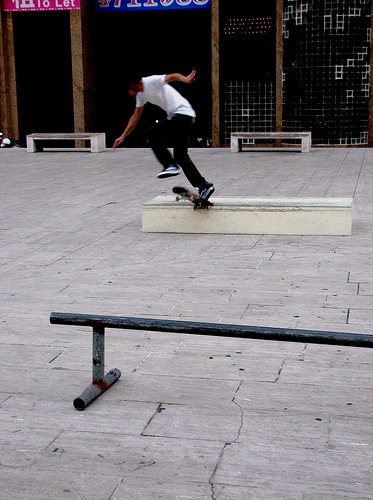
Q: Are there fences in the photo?
A: No, there are no fences.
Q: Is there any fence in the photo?
A: No, there are no fences.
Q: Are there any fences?
A: No, there are no fences.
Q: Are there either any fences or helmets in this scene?
A: No, there are no fences or helmets.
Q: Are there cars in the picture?
A: No, there are no cars.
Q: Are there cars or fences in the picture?
A: No, there are no cars or fences.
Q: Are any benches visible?
A: Yes, there is a bench.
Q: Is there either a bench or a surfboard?
A: Yes, there is a bench.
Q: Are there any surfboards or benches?
A: Yes, there is a bench.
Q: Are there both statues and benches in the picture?
A: No, there is a bench but no statues.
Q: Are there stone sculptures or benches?
A: Yes, there is a stone bench.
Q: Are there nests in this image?
A: No, there are no nests.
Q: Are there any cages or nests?
A: No, there are no nests or cages.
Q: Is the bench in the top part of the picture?
A: Yes, the bench is in the top of the image.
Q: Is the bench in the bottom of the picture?
A: No, the bench is in the top of the image.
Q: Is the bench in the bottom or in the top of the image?
A: The bench is in the top of the image.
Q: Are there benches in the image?
A: Yes, there is a bench.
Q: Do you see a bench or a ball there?
A: Yes, there is a bench.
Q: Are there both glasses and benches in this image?
A: No, there is a bench but no glasses.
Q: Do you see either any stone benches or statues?
A: Yes, there is a stone bench.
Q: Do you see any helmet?
A: No, there are no helmets.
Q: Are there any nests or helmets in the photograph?
A: No, there are no helmets or nests.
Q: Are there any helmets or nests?
A: No, there are no helmets or nests.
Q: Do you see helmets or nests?
A: No, there are no helmets or nests.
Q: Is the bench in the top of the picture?
A: Yes, the bench is in the top of the image.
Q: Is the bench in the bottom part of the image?
A: No, the bench is in the top of the image.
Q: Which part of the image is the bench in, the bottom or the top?
A: The bench is in the top of the image.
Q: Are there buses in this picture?
A: No, there are no buses.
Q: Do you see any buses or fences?
A: No, there are no buses or fences.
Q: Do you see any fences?
A: No, there are no fences.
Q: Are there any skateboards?
A: Yes, there is a skateboard.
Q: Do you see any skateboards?
A: Yes, there is a skateboard.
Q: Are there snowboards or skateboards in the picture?
A: Yes, there is a skateboard.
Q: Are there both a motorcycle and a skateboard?
A: No, there is a skateboard but no motorcycles.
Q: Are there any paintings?
A: No, there are no paintings.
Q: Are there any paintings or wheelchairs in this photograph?
A: No, there are no paintings or wheelchairs.